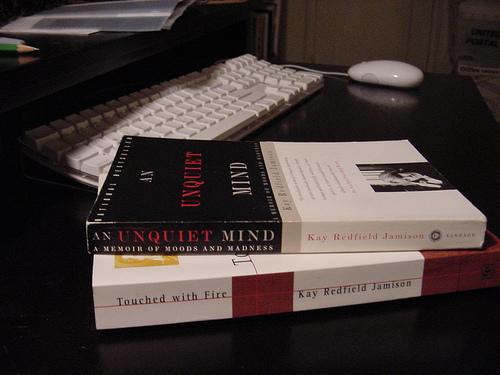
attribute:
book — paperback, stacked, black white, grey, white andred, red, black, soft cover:
[85, 135, 488, 250]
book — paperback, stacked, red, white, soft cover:
[92, 173, 499, 330]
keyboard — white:
[16, 52, 325, 190]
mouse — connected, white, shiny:
[348, 58, 425, 90]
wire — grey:
[279, 62, 347, 78]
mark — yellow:
[112, 250, 181, 267]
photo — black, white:
[355, 163, 455, 194]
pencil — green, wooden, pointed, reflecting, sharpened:
[0, 41, 39, 54]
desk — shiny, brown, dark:
[1, 3, 499, 374]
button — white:
[22, 123, 60, 150]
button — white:
[43, 136, 72, 162]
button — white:
[62, 143, 99, 169]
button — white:
[81, 154, 115, 176]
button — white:
[50, 117, 76, 135]